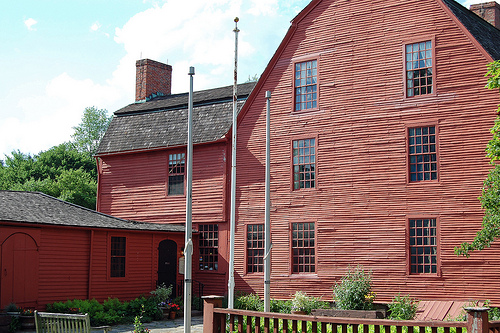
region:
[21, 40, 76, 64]
this is the sky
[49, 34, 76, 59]
the sky is blue in color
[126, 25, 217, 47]
the sky has some clouds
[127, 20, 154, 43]
the clouds are white in color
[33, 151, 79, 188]
this is a tree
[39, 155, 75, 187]
the leaves are green in color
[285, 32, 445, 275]
these are several windows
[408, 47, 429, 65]
the window has curtains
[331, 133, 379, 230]
the wall is brown in color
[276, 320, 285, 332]
the grass is green in color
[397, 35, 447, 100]
Windows in the side of an old barn House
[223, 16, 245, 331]
Flagpole that flies no flag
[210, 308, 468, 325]
Top rail of wooden fence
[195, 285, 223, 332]
Support post for wooden fence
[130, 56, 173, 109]
Brick chimney sticking out of rooftop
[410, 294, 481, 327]
Old coal door for coal heat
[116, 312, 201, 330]
Walkway made from cobblestone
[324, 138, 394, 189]
Very old wooden siding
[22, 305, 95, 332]
Park bench sitting on the patio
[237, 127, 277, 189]
Shadow cast by rooftop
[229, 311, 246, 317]
the fence is red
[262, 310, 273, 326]
the fence is red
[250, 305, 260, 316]
the fence is red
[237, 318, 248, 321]
the fence is red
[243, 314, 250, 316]
the fence is red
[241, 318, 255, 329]
the fence is red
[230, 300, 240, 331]
the fence is red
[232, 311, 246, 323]
the fence is red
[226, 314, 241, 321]
the fence is red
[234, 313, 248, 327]
the fence is red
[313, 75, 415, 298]
the wall is made of bamboo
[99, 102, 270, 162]
the roof isblack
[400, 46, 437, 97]
curtains on the windows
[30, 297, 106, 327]
bench facing the building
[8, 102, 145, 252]
trees behind the building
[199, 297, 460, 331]
the fence is brown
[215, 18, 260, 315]
the pole is white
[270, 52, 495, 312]
the windows are closed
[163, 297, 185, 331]
flower in a pot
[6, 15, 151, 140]
the sky is clear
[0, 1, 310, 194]
the sky is cloudy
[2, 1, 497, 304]
the building is a reddish brown color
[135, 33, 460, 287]
the building has windows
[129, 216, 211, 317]
the door is black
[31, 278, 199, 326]
bushes alongside the building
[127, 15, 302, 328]
the poles are white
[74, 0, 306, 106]
the clouds are white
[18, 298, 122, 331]
the bench is brown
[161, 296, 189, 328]
red flowers in a pot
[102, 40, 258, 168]
the building has a chimney